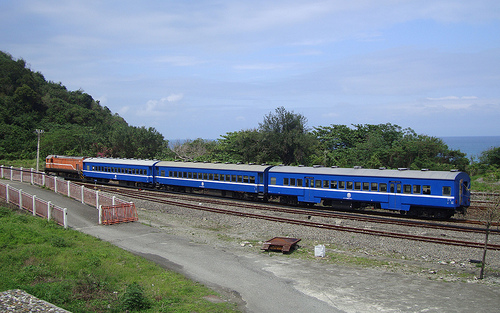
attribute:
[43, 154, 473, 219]
train — blue, moving, long, orange, gray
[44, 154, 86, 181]
car — red, orange, white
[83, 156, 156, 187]
car — blue, long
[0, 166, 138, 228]
fence — red, white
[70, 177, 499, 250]
tracks — brown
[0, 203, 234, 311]
grass — long, green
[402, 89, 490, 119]
clouds — wispy, white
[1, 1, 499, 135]
sky — blue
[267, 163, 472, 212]
car — long, blue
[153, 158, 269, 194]
car — long, blue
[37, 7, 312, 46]
clouds — white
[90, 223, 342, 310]
pathway — gray, concrete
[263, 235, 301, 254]
metal — brown, rusted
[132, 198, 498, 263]
gravel — gray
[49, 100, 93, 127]
bushes — tall, green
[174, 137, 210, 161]
bush — dead, brown, bare, small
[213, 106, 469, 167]
brush — green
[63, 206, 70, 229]
post — white